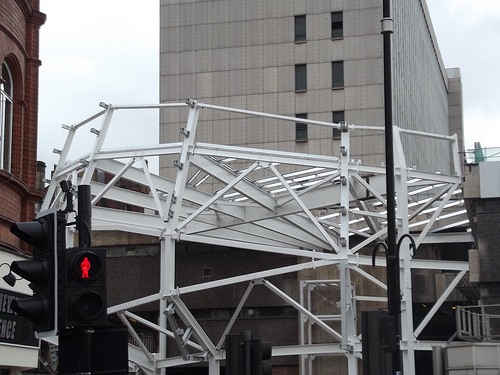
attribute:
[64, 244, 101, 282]
person — red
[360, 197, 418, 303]
hooks — black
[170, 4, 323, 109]
building — tall, side, designed, gray, brick, multi story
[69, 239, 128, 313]
signal — painted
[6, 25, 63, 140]
brick — red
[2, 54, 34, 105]
window — arched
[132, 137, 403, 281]
metal — white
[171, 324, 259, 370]
letters — white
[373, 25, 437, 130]
pole — black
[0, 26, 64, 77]
building — brown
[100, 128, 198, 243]
scaffolding — metal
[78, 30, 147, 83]
sky — cloudy, cloud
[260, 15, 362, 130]
windows — small, here, six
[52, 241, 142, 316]
light — traffic, here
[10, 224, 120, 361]
signals — present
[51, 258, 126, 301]
man — red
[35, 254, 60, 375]
lights — black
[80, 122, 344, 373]
structure — white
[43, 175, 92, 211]
camera — traffic